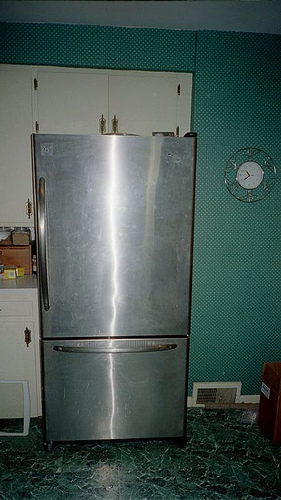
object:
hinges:
[26, 76, 48, 134]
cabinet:
[33, 67, 193, 136]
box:
[1, 266, 17, 279]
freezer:
[29, 122, 197, 443]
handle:
[51, 343, 177, 352]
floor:
[2, 408, 280, 500]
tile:
[9, 391, 267, 498]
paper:
[196, 272, 263, 363]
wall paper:
[1, 0, 194, 441]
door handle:
[24, 327, 32, 348]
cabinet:
[1, 278, 42, 438]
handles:
[243, 169, 252, 181]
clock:
[223, 144, 279, 203]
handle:
[35, 175, 51, 311]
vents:
[192, 382, 240, 408]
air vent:
[193, 380, 241, 406]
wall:
[192, 25, 276, 403]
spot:
[89, 465, 121, 487]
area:
[0, 0, 281, 500]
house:
[1, 0, 278, 499]